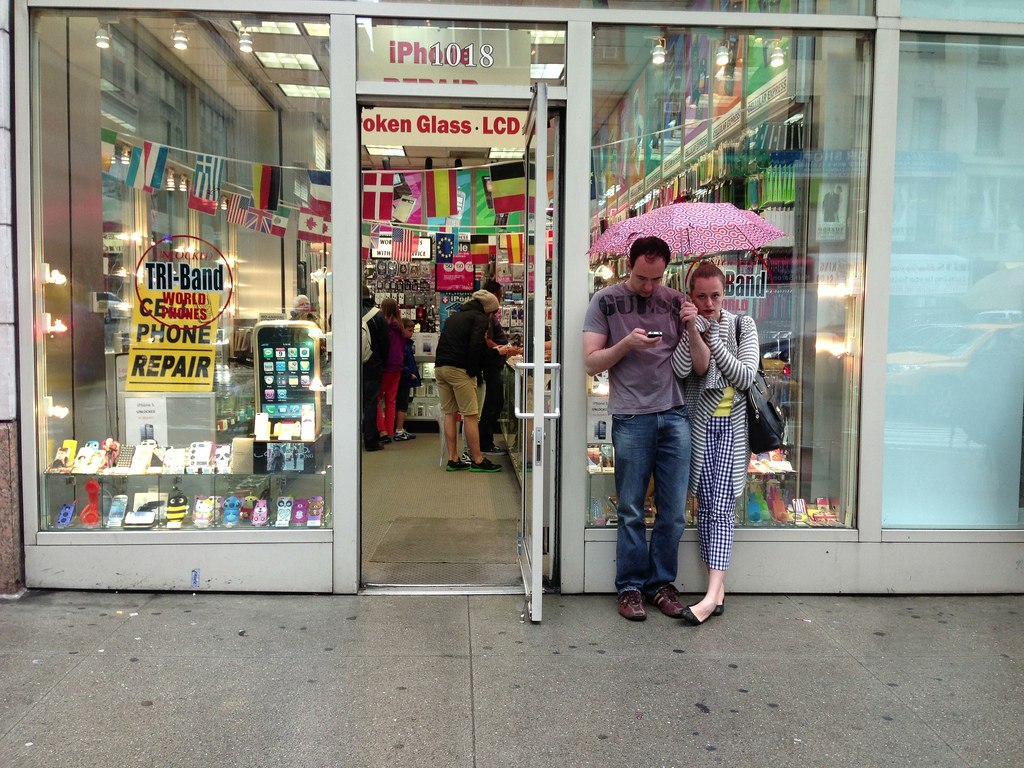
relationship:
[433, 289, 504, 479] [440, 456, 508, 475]
person wearing shoes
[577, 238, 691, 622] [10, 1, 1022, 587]
man standing next to store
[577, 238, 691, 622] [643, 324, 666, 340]
man looking at phone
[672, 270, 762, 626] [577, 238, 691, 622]
woman next to man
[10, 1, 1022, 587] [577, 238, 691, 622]
store behind man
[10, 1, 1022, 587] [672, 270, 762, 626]
store behind woman